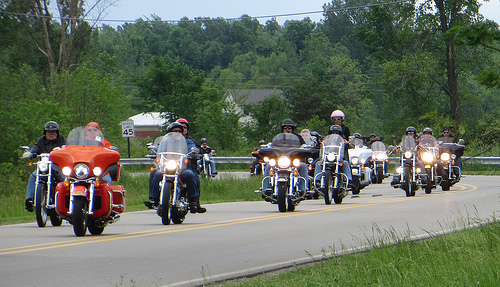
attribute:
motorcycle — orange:
[47, 122, 132, 232]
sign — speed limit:
[112, 109, 154, 151]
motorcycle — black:
[252, 144, 322, 208]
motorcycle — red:
[55, 124, 117, 239]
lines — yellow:
[2, 157, 476, 263]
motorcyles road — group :
[18, 105, 468, 237]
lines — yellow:
[25, 235, 87, 252]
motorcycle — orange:
[48, 132, 123, 224]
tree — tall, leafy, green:
[17, 3, 103, 89]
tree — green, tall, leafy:
[123, 29, 144, 101]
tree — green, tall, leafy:
[142, 54, 208, 127]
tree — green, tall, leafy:
[289, 67, 362, 131]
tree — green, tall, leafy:
[416, 0, 481, 140]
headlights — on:
[157, 148, 185, 180]